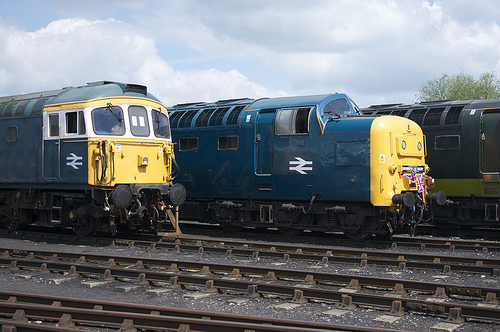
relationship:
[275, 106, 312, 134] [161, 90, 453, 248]
window on train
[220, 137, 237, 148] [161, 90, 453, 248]
window on train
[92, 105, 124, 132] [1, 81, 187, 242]
window on train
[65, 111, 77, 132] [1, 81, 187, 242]
window on train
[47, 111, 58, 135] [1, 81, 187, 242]
window on train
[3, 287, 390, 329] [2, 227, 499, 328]
tracks on ground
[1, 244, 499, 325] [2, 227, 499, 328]
tracks on ground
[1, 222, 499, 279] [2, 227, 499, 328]
tracks on ground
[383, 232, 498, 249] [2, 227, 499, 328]
tracks on ground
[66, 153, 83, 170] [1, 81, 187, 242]
logo on train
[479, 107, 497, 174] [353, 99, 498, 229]
door on train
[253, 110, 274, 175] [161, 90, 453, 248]
door on train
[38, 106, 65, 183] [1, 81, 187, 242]
door on train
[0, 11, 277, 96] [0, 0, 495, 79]
cloud in sky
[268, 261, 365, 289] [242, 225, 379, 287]
rocks next to track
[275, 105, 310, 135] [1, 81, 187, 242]
window on side of train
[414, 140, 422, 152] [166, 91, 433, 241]
lights of front of train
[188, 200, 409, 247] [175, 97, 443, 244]
bottom of train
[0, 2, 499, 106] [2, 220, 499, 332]
sky above ground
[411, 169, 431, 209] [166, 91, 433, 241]
flag in front of train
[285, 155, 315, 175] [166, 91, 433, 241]
logo on train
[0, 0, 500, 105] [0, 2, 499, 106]
clouds in sky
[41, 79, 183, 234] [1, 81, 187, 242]
train front of train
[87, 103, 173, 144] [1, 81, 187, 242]
windows on front of train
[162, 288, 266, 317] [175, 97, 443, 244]
rocks next to train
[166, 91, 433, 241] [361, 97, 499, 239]
train next to train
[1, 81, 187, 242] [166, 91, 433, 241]
train next to train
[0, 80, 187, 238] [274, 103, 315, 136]
train has windows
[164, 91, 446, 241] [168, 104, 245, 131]
train has windows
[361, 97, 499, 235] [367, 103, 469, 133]
trains has windows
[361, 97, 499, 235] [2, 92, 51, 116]
trains has windows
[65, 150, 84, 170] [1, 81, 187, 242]
logo on side of train